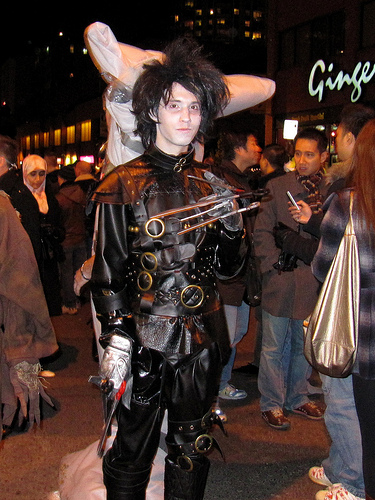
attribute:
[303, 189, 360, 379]
bag — bronze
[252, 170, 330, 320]
coat — long , gray 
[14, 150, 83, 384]
woman — long black coat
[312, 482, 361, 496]
shoes — white, pair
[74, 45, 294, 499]
guy — black hair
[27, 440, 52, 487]
floor — concrete 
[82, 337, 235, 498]
pants — black leather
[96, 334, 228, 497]
pants — leather , pair 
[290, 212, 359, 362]
bag — gold 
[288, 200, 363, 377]
bag — gold 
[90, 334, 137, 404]
glove — silver 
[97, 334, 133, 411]
glove — silver